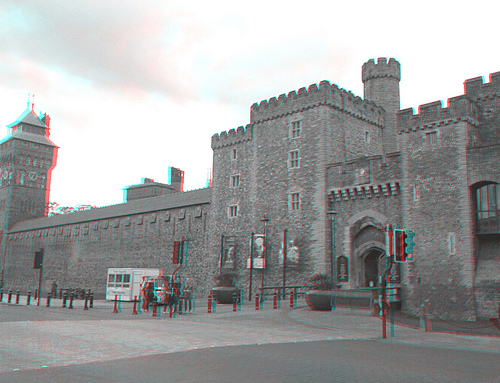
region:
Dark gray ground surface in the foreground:
[1, 338, 498, 378]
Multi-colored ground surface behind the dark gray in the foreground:
[1, 321, 380, 338]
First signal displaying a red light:
[376, 221, 416, 339]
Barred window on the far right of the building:
[468, 179, 499, 237]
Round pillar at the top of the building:
[361, 54, 402, 150]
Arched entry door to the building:
[363, 246, 384, 286]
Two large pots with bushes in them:
[211, 271, 333, 309]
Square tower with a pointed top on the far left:
[0, 103, 52, 218]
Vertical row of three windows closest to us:
[286, 120, 303, 214]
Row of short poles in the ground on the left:
[1, 292, 96, 309]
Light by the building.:
[317, 211, 482, 342]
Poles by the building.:
[60, 274, 240, 376]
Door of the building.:
[335, 209, 431, 326]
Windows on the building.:
[205, 122, 388, 272]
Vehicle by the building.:
[85, 250, 219, 349]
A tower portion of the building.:
[5, 112, 156, 297]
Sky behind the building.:
[92, 129, 359, 291]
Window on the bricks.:
[463, 164, 491, 261]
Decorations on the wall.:
[216, 203, 344, 297]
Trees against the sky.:
[47, 187, 167, 225]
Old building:
[171, 47, 461, 348]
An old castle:
[256, 111, 445, 299]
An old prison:
[171, 106, 414, 346]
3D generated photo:
[31, 110, 381, 380]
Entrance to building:
[331, 215, 426, 374]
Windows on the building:
[274, 116, 309, 226]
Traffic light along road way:
[371, 225, 409, 378]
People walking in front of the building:
[114, 274, 198, 326]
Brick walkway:
[67, 84, 254, 376]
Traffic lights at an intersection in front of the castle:
[22, 227, 493, 361]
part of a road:
[266, 332, 301, 363]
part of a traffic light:
[390, 222, 425, 296]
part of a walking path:
[212, 322, 249, 340]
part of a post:
[371, 280, 393, 335]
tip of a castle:
[361, 50, 398, 90]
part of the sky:
[60, 146, 95, 187]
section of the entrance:
[362, 255, 382, 275]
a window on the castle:
[283, 146, 300, 166]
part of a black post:
[35, 260, 44, 302]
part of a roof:
[17, 115, 37, 122]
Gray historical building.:
[3, 56, 498, 333]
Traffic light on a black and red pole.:
[370, 225, 415, 340]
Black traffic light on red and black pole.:
[394, 228, 409, 262]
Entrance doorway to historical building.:
[351, 212, 390, 296]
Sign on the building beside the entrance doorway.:
[330, 253, 350, 285]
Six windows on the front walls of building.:
[210, 117, 323, 246]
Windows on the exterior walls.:
[218, 117, 314, 223]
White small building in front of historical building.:
[105, 266, 162, 301]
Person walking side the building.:
[45, 275, 60, 305]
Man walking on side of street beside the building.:
[42, 277, 64, 301]